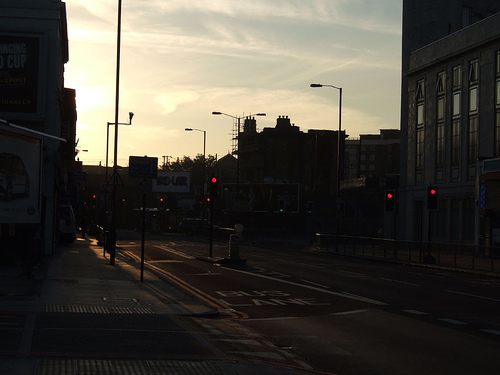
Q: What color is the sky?
A: Blue.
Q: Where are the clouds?
A: Sky.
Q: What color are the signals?
A: Red.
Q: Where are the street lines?
A: On road.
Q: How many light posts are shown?
A: Five.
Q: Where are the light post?
A: Sidewalk.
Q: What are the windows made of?
A: Glass.